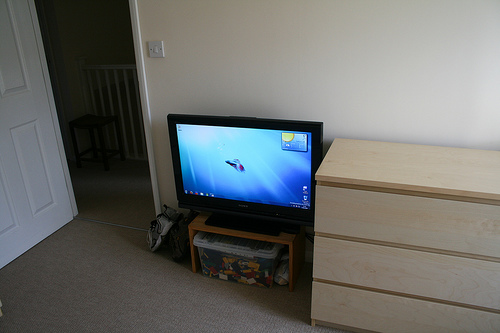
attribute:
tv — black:
[168, 112, 324, 221]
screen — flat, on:
[176, 123, 314, 210]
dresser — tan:
[311, 135, 498, 321]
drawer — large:
[312, 182, 498, 259]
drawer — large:
[311, 233, 499, 313]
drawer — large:
[309, 280, 494, 328]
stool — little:
[68, 110, 128, 171]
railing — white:
[75, 60, 154, 160]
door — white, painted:
[0, 0, 77, 270]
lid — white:
[192, 229, 285, 260]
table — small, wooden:
[188, 211, 308, 290]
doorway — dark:
[34, 0, 166, 233]